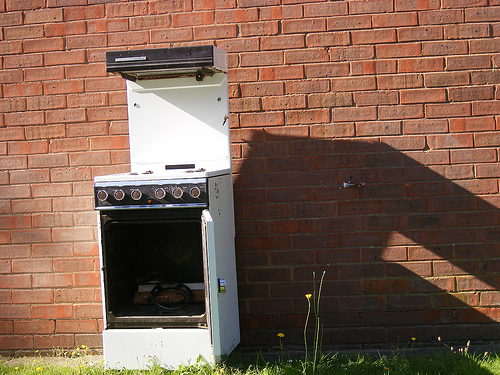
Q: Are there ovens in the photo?
A: Yes, there is an oven.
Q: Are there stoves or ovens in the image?
A: Yes, there is an oven.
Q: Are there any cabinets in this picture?
A: No, there are no cabinets.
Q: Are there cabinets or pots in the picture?
A: No, there are no cabinets or pots.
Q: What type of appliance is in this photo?
A: The appliance is an oven.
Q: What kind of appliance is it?
A: The appliance is an oven.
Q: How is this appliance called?
A: This is an oven.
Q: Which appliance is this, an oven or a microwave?
A: This is an oven.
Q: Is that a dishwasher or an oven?
A: That is an oven.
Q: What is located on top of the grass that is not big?
A: The oven is on top of the grass.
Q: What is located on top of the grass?
A: The oven is on top of the grass.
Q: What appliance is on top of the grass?
A: The appliance is an oven.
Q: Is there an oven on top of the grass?
A: Yes, there is an oven on top of the grass.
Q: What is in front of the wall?
A: The oven is in front of the wall.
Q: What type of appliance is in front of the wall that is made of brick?
A: The appliance is an oven.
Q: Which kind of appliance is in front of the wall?
A: The appliance is an oven.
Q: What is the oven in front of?
A: The oven is in front of the wall.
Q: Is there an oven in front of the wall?
A: Yes, there is an oven in front of the wall.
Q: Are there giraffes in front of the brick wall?
A: No, there is an oven in front of the wall.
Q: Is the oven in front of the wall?
A: Yes, the oven is in front of the wall.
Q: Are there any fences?
A: No, there are no fences.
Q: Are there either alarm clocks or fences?
A: No, there are no fences or alarm clocks.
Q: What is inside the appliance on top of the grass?
A: The wire is inside the oven.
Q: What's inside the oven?
A: The wire is inside the oven.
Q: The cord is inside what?
A: The cord is inside the oven.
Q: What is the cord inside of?
A: The cord is inside the oven.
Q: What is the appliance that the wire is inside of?
A: The appliance is an oven.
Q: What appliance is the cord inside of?
A: The wire is inside the oven.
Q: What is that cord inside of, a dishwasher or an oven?
A: The cord is inside an oven.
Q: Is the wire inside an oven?
A: Yes, the wire is inside an oven.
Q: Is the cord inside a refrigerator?
A: No, the cord is inside an oven.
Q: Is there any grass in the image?
A: Yes, there is grass.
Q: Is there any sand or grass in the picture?
A: Yes, there is grass.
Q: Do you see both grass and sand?
A: No, there is grass but no sand.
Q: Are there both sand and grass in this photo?
A: No, there is grass but no sand.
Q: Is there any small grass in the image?
A: Yes, there is small grass.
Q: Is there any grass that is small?
A: Yes, there is grass that is small.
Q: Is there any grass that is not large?
A: Yes, there is small grass.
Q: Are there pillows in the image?
A: No, there are no pillows.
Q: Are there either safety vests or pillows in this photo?
A: No, there are no pillows or safety vests.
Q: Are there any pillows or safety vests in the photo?
A: No, there are no pillows or safety vests.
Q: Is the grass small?
A: Yes, the grass is small.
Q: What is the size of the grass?
A: The grass is small.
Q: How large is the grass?
A: The grass is small.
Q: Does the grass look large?
A: No, the grass is small.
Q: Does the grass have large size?
A: No, the grass is small.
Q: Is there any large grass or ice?
A: No, there is grass but it is small.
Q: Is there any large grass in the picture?
A: No, there is grass but it is small.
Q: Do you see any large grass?
A: No, there is grass but it is small.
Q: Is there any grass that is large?
A: No, there is grass but it is small.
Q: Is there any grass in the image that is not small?
A: No, there is grass but it is small.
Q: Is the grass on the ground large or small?
A: The grass is small.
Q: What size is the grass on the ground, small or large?
A: The grass is small.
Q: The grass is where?
A: The grass is on the ground.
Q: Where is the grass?
A: The grass is on the ground.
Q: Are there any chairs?
A: No, there are no chairs.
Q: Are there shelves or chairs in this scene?
A: No, there are no chairs or shelves.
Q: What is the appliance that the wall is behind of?
A: The appliance is an oven.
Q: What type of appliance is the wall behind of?
A: The wall is behind the oven.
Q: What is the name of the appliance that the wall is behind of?
A: The appliance is an oven.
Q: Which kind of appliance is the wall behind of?
A: The wall is behind the oven.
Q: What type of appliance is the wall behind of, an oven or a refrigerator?
A: The wall is behind an oven.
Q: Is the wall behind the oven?
A: Yes, the wall is behind the oven.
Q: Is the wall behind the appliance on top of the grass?
A: Yes, the wall is behind the oven.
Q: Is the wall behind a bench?
A: No, the wall is behind the oven.